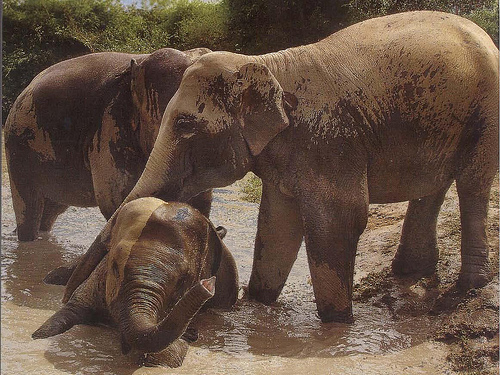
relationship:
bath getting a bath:
[31, 197, 242, 367] [31, 197, 239, 367]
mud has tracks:
[347, 164, 499, 374] [355, 165, 500, 374]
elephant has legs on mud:
[62, 9, 500, 324] [347, 164, 499, 374]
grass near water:
[236, 170, 263, 204] [0, 121, 457, 374]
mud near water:
[347, 164, 499, 374] [0, 121, 457, 374]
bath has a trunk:
[31, 197, 242, 367] [109, 274, 217, 354]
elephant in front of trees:
[62, 9, 500, 324] [1, 0, 500, 128]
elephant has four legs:
[62, 9, 500, 324] [246, 179, 494, 324]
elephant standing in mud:
[62, 9, 500, 324] [347, 164, 499, 374]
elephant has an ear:
[62, 9, 500, 324] [238, 64, 294, 157]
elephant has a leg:
[62, 9, 500, 324] [281, 158, 371, 324]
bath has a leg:
[31, 197, 242, 367] [31, 273, 100, 341]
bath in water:
[31, 197, 242, 367] [0, 121, 457, 374]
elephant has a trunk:
[62, 9, 500, 324] [63, 107, 201, 304]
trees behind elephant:
[1, 0, 500, 128] [62, 9, 500, 324]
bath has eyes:
[31, 197, 242, 367] [111, 260, 186, 291]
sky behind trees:
[93, 0, 225, 13] [1, 0, 500, 128]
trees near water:
[1, 0, 500, 128] [0, 121, 457, 374]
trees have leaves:
[1, 0, 500, 128] [0, 1, 499, 127]